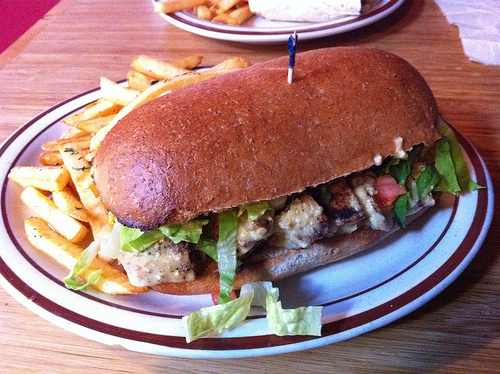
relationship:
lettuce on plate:
[180, 281, 324, 344] [0, 65, 494, 358]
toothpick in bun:
[287, 30, 298, 84] [92, 46, 443, 295]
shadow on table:
[105, 123, 498, 373] [0, 0, 499, 373]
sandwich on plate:
[92, 45, 485, 295] [0, 65, 494, 358]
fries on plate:
[8, 52, 249, 296] [0, 65, 494, 358]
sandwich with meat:
[92, 45, 485, 295] [120, 168, 397, 288]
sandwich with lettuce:
[92, 45, 485, 295] [65, 115, 487, 344]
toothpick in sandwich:
[287, 30, 298, 84] [92, 45, 485, 295]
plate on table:
[0, 65, 494, 358] [0, 0, 499, 373]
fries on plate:
[154, 0, 254, 28] [153, 0, 406, 44]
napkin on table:
[433, 1, 499, 67] [0, 0, 499, 373]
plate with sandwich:
[0, 65, 494, 358] [92, 45, 485, 295]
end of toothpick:
[287, 37, 298, 69] [287, 30, 298, 84]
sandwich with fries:
[92, 45, 485, 295] [8, 52, 249, 296]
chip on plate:
[112, 342, 129, 351] [0, 65, 494, 358]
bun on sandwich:
[92, 46, 443, 295] [92, 45, 485, 295]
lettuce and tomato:
[180, 281, 324, 344] [376, 175, 407, 212]